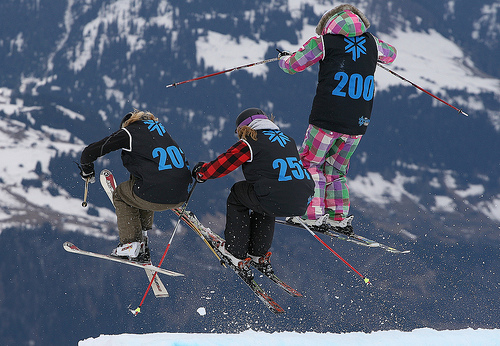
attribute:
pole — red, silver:
[167, 53, 287, 89]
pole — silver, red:
[376, 62, 464, 115]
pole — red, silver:
[135, 177, 204, 310]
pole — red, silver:
[293, 218, 368, 286]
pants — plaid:
[300, 120, 362, 232]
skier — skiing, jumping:
[64, 7, 468, 314]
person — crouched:
[79, 107, 191, 260]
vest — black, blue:
[309, 33, 376, 134]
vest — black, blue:
[240, 128, 313, 215]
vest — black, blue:
[123, 111, 192, 205]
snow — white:
[78, 324, 496, 345]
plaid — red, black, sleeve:
[197, 140, 249, 183]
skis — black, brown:
[276, 206, 411, 255]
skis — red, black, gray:
[171, 206, 300, 311]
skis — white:
[62, 169, 184, 298]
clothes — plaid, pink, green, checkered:
[278, 11, 395, 219]